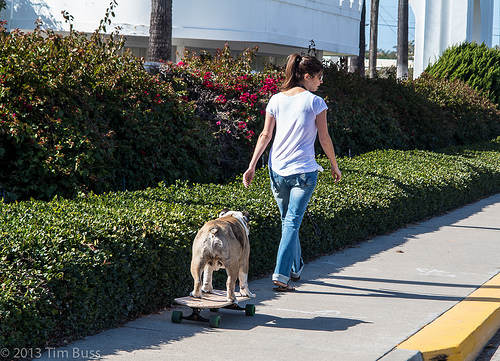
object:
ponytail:
[278, 53, 303, 90]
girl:
[228, 26, 380, 335]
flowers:
[167, 60, 280, 139]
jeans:
[269, 168, 318, 285]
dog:
[188, 210, 252, 303]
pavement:
[27, 192, 500, 361]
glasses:
[310, 74, 324, 81]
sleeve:
[309, 95, 328, 115]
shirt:
[265, 90, 329, 177]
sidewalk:
[33, 193, 500, 361]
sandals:
[273, 276, 301, 292]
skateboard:
[171, 290, 256, 328]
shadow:
[219, 313, 373, 332]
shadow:
[287, 279, 500, 303]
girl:
[242, 52, 341, 292]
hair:
[279, 52, 324, 91]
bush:
[0, 136, 500, 361]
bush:
[0, 0, 497, 200]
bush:
[420, 37, 500, 106]